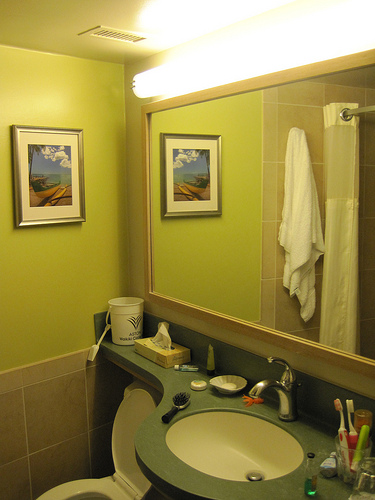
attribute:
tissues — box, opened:
[149, 322, 177, 353]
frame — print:
[9, 121, 86, 227]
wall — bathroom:
[2, 58, 130, 374]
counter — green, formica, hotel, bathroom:
[96, 337, 373, 499]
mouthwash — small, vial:
[298, 449, 322, 495]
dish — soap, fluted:
[208, 372, 250, 395]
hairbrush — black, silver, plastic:
[159, 391, 190, 422]